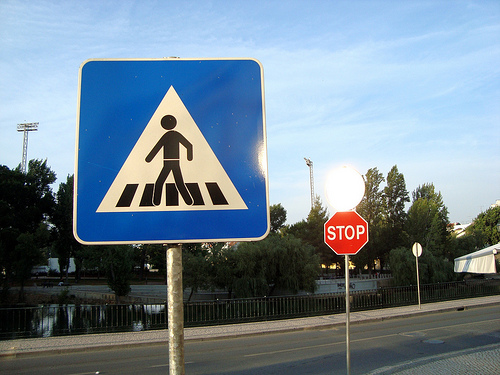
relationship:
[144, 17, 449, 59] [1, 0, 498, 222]
clouds in sky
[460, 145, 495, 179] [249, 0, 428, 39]
white cloud in blue sky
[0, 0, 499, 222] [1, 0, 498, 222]
clouds in sky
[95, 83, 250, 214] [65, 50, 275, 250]
triangle on sign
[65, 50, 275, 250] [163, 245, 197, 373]
sign on pole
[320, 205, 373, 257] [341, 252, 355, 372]
sign on pole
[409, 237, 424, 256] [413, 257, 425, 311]
sign on pole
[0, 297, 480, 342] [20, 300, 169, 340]
lake in town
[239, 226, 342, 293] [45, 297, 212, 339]
tree reflecting in water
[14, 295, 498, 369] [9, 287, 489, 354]
road with sidewalk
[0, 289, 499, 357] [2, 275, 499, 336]
sidewalk with railing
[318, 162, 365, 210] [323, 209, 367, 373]
white light on top of stop sign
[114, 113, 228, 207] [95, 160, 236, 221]
figure on a crossing strip